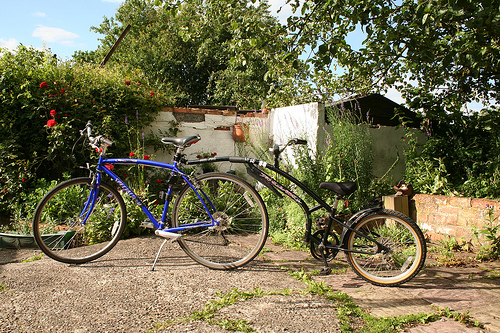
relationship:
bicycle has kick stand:
[31, 119, 428, 287] [137, 226, 179, 273]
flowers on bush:
[36, 76, 172, 190] [0, 52, 165, 199]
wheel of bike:
[171, 172, 269, 271] [31, 117, 269, 272]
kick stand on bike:
[149, 236, 167, 271] [20, 124, 270, 311]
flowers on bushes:
[36, 77, 164, 186] [1, 41, 189, 201]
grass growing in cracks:
[1, 251, 42, 262] [0, 230, 480, 331]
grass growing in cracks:
[292, 266, 313, 296] [0, 230, 480, 331]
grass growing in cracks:
[341, 293, 355, 328] [0, 230, 480, 331]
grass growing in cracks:
[226, 289, 296, 300] [0, 230, 480, 331]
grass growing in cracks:
[198, 310, 253, 329] [0, 230, 480, 331]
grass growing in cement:
[282, 264, 399, 330] [2, 226, 497, 330]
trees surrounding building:
[7, 33, 498, 166] [133, 92, 423, 187]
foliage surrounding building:
[0, 0, 500, 264] [133, 92, 423, 187]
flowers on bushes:
[321, 88, 375, 178] [313, 94, 365, 171]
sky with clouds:
[18, 0, 139, 54] [22, 0, 124, 60]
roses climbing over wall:
[39, 72, 107, 131] [125, 107, 273, 170]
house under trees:
[140, 89, 432, 192] [92, 14, 498, 111]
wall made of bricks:
[378, 186, 498, 258] [442, 194, 466, 207]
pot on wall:
[233, 124, 247, 146] [138, 112, 266, 172]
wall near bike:
[378, 186, 498, 258] [162, 134, 431, 286]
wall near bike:
[378, 186, 498, 258] [31, 117, 269, 272]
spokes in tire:
[52, 225, 70, 257] [27, 179, 134, 266]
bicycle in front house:
[31, 119, 428, 287] [140, 89, 420, 188]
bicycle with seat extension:
[31, 119, 428, 287] [180, 141, 424, 286]